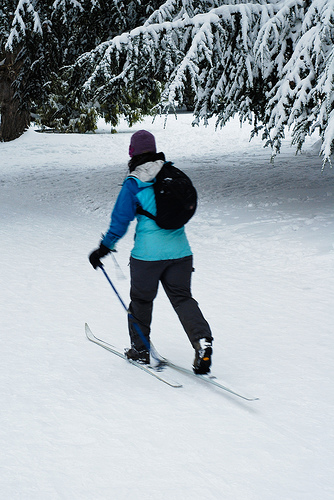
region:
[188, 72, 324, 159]
Snow on tree limbs.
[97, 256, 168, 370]
Blue ski pole.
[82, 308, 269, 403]
Pair of cross country skis.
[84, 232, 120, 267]
Black glove on left hand.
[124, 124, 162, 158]
Winter hat on person's head.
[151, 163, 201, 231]
Black backpack on skier's back.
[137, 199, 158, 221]
Black strap attached to backpack.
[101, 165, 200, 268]
Two colors on winter coat.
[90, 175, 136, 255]
Long blue coat sleeve.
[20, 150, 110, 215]
Tracks in the snow.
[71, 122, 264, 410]
Woman is standing on packed snow.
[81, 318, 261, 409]
Woman is wearing skis.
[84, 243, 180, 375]
Woman is holding ski pole.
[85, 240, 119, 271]
Woman is wearing gloves.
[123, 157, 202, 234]
Woman is carrying a backpack.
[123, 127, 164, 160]
Woman is wearing knitted cap.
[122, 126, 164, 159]
Knitted cap is purple.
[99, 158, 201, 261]
Woman is wearing a jacket.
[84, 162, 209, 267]
The woman's jacket is two-tone.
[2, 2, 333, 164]
Pine trees covered with dusting of snow.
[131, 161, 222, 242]
the backpack is black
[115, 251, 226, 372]
the pants are black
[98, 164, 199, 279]
the jacket is blue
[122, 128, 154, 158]
the cap is purple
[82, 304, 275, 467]
the ski board is white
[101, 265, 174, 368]
the ski pole is blue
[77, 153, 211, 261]
the woman is carrying a backpack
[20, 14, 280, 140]
the trees are covered in snow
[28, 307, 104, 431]
the snow is white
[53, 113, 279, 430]
the person is skiing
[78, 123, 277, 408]
back of cross country skier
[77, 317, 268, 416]
two skis attached to boots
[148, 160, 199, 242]
skier wearing black backpack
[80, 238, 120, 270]
glove on skier's hand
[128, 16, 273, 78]
tree branches covered in snow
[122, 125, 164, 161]
purple cap on skier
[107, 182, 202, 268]
two toned blue jacket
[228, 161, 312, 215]
shadow of tree on snow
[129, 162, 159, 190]
hood on back of jacket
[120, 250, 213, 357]
gray pants on skier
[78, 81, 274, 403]
skier approaching trees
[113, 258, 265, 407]
right foot lifted on ski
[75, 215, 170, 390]
pole outside of left leg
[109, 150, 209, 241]
backpack slung to one side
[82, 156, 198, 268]
different blue colors on jacket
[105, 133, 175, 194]
hood hanging behind head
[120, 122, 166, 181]
skier wearing grey knitted cap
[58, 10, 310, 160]
branches covered in snow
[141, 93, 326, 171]
tips of evergreen branches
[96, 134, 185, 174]
black collar around skier's neck